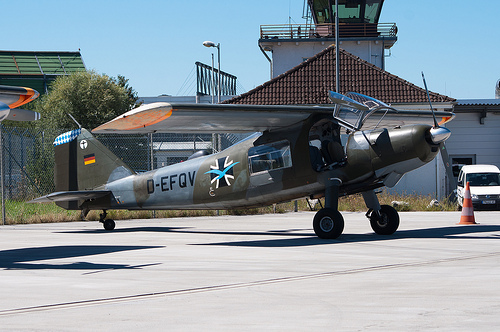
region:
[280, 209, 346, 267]
blacvk tire with silver rim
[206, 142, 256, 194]
painting on side of plane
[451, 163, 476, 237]
orange and white traffic cone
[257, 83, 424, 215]
two open doors of a plane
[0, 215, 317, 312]
shadow on the ground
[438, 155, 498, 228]
white parked vehicle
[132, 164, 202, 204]
black letters on side of plane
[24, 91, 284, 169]
the wing of a plane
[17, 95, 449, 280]
small plane on a runway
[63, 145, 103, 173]
yellow black and orange sticker on plane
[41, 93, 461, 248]
airplane sitting on the tarmac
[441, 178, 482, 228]
orange and white stripes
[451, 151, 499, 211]
white van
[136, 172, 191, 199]
black writing on the side of the plane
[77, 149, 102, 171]
black, red, and yellow flag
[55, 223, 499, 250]
shadow from the plane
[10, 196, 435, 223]
patch of brown grass along the fence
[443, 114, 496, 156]
white siding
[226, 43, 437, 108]
brown roof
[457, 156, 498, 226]
white van facing camera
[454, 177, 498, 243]
orange and white safety cone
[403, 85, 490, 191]
silver propeller on front of airplane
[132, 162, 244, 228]
letters d-efqv on side of airplane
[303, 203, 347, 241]
right front tire on airplane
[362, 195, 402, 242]
left front tire on airplane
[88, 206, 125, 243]
back rear tire on airplane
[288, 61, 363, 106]
brown tile roof on building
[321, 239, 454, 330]
concrete with line infront of airplane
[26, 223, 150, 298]
airplane shadow on left side of photo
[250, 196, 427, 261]
landing wheels on a plane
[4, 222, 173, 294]
shadow of a plane on the ground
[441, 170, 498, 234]
an orange cone on the ground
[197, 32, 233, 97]
a light post in the air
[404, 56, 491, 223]
propeller on the airplane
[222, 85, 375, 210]
cockpit of the plane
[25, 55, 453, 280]
a brown airplane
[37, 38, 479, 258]
an airplane landed on the ground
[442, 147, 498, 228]
a parked white van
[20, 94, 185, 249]
tail of a plane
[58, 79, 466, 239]
a vintage airplane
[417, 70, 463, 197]
a silver propeller blade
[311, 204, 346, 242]
a black plane tire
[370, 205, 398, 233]
a black plane tire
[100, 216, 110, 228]
a black plane tire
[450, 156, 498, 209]
a white minivan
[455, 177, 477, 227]
a white and orange traffic cone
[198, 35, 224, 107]
an overhead street light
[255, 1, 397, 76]
an airport flight tower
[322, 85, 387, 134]
a open cockpit cover